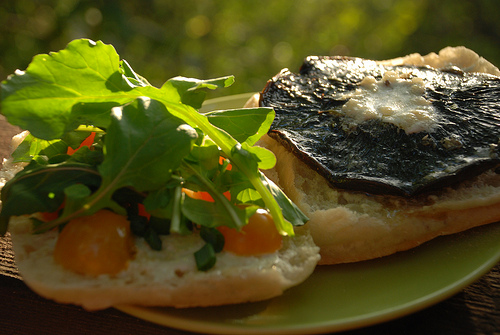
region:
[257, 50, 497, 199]
Mushroom on bread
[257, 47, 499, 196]
Mushroom is on bread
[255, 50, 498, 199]
Portabella mushroom on bread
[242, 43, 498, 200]
Portabella mushroom is on bread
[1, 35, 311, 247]
Greens on bread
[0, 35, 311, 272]
Greens are on bread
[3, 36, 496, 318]
Bread on a plate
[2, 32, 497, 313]
Bread is on a plate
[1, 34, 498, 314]
Bread on a green plate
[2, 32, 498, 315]
Bread is on a green plate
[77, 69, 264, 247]
green lettuce on sandwich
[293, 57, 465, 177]
brown mushroom on sandwich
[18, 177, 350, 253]
small orange vegetables on sandwich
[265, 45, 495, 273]
white bread for sandwich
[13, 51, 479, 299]
white bread is halved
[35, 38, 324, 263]
green lettuce is leafy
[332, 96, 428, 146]
white base on mushrooms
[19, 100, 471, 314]
plate is round and green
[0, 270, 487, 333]
plate on brown table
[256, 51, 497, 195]
a large mushroom slice on the sandwich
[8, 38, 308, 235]
lettuce leaves on the sandwich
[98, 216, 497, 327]
the plate under the sandwich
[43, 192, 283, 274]
tomato halves on the sandwich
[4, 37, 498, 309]
a disgusting vegetarian sandwich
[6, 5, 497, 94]
a blurry backdrop behind the sandwich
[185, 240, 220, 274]
green onion on the sandwich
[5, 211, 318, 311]
a bun holds half of the sandwich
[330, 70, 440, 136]
the white center of the mushroom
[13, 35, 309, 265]
vegetables on the sandwich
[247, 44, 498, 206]
portobella mushroom on bread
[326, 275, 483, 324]
green plate where food is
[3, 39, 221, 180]
lettuce on a sandwich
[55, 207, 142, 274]
tomato on a sandwich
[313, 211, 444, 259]
white bread of a sandwich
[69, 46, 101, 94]
light shining on lettuce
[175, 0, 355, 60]
blur on green leaves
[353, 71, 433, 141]
middle of a mushroom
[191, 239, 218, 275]
chive on a sandwich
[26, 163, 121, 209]
shadow casted on a piece of lettuce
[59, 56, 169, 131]
green shadowy leaf on top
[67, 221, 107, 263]
round orange tomato on bread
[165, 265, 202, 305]
slice of thick bread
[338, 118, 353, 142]
dark mushroom on white bread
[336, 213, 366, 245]
white bread is toasted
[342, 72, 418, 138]
white stem spot on mushroom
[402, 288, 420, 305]
round green dinner plate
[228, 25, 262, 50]
green blurry background behind plate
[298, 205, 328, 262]
open sandwich on plate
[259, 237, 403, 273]
meatless sandwich on dinner plate